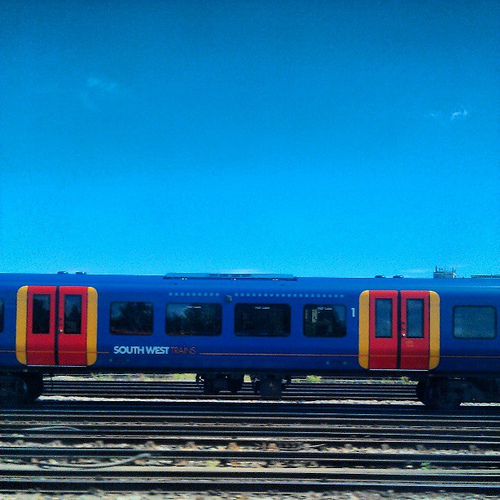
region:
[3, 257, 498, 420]
The train is colorful.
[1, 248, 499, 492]
The train sitting on the tracks.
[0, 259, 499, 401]
The doors on the train are closed.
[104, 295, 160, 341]
The window is rectangular.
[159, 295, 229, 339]
The window is rectangular.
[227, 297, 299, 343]
The window is rectangular.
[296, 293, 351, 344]
The window is rectangular.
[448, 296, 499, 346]
The window is rectangular.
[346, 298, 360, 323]
The number is blue.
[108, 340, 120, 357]
The letter is blue.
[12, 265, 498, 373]
the side of a train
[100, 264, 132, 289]
the ceiling of a blue train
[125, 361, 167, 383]
the bottom of a blue train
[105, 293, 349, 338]
the windows of a blue train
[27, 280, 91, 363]
the doors of a blue train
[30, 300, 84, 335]
the door windows of a blue train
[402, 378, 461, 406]
the wheels of a blue train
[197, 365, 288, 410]
the engine of a blue train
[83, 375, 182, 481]
the train tracks of a blue train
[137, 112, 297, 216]
a very clear blue sky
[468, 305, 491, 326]
window of a train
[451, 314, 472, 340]
window of a train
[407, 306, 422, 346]
window of a train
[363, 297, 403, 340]
window of a train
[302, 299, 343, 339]
window of a train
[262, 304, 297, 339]
window of a train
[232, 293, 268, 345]
window of a train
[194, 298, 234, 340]
window of a train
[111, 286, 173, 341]
window of a train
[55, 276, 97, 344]
window of a train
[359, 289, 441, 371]
two passenger doors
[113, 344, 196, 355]
logo on the train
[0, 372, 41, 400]
black train wheels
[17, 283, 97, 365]
the doors are closed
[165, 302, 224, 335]
a passenger window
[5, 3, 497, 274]
clear blue skies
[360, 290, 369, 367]
yellow trim on the door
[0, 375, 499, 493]
multiple train tracks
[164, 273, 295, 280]
vent on the roof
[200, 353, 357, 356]
thin accent line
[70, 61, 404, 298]
the sky is cloudy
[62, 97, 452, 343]
the sky is clear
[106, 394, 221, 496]
the tracks are metal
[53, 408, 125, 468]
rocks are underneath the tracks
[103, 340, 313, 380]
white writing is on the train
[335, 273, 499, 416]
the doors are red and yellow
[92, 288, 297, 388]
the train is blue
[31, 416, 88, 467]
sticks are on the track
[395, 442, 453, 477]
grass is on the track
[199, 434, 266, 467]
leaves are on the track